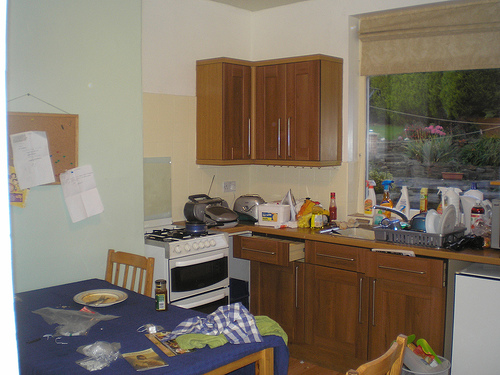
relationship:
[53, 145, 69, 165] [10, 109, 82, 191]
push pins in cork boad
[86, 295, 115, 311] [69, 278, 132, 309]
2 utensils on dishes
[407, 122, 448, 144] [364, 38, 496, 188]
flowers in garden outside kitchen window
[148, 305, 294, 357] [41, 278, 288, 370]
cloths are on top of table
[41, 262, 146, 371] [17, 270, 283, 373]
dishes are on top of table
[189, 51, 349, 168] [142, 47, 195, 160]
cabinet attached to wall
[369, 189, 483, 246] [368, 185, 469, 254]
dishes are inside drain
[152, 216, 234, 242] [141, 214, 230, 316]
pan on top of stove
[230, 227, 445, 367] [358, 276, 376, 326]
kitchen cabinets with pulls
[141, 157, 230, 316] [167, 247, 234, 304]
stove with oven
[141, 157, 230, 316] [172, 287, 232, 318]
stove with oven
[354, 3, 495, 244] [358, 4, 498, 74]
window with shade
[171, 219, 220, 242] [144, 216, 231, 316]
pan atop range